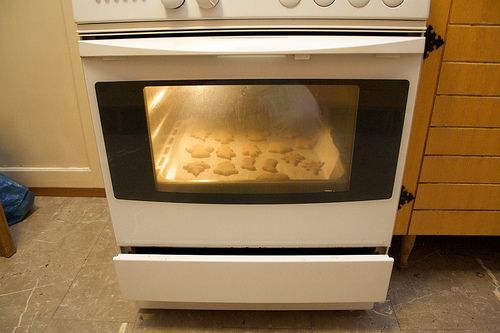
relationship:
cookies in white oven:
[178, 117, 328, 182] [65, 32, 429, 247]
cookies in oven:
[178, 117, 328, 182] [94, 72, 410, 210]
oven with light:
[94, 72, 410, 210] [170, 81, 241, 101]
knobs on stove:
[199, 0, 219, 14] [61, 1, 441, 304]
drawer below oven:
[111, 246, 395, 311] [94, 72, 410, 210]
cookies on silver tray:
[178, 117, 328, 182] [156, 130, 187, 189]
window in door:
[77, 26, 427, 132] [75, 28, 442, 61]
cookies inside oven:
[178, 117, 328, 182] [94, 72, 410, 210]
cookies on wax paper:
[178, 117, 328, 182] [321, 138, 343, 171]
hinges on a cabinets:
[399, 23, 467, 216] [393, 6, 497, 243]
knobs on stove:
[159, 1, 409, 18] [61, 1, 441, 304]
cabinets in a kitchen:
[393, 6, 497, 243] [1, 0, 496, 331]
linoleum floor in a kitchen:
[1, 193, 500, 330] [1, 0, 496, 331]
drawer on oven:
[111, 246, 395, 311] [94, 72, 410, 210]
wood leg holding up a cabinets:
[397, 231, 420, 269] [393, 6, 497, 243]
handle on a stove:
[77, 35, 428, 55] [61, 1, 441, 304]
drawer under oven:
[111, 246, 395, 311] [94, 72, 410, 210]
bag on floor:
[0, 165, 39, 219] [31, 192, 114, 322]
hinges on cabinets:
[399, 23, 467, 216] [393, 6, 497, 243]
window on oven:
[77, 26, 427, 132] [94, 72, 410, 210]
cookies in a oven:
[178, 117, 328, 182] [94, 72, 410, 210]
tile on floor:
[32, 193, 112, 330] [31, 192, 114, 322]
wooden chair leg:
[4, 227, 6, 229] [1, 208, 17, 259]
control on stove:
[159, 1, 409, 18] [61, 1, 441, 304]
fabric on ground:
[11, 193, 21, 206] [3, 255, 107, 330]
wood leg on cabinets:
[397, 231, 420, 269] [393, 6, 497, 243]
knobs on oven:
[199, 0, 219, 14] [94, 72, 410, 210]